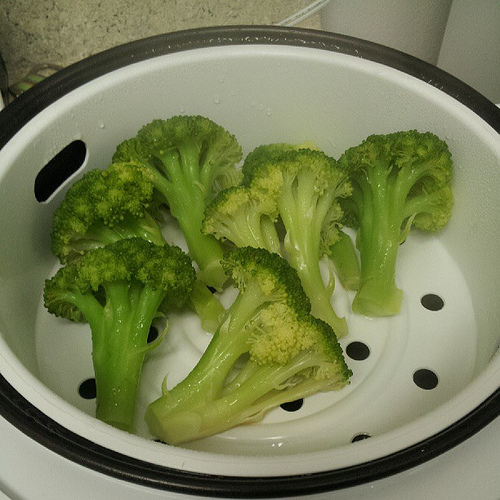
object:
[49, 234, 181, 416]
broccoli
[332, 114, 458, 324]
broccoli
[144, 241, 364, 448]
broccoli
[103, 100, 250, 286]
broccoli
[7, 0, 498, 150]
reflection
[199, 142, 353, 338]
broccoli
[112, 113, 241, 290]
broccoli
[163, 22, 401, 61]
rim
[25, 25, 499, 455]
steamer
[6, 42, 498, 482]
bowl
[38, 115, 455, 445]
broccoli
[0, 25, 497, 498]
steamer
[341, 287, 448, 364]
steam holes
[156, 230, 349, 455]
green broccoli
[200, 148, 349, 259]
broccoli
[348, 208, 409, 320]
stem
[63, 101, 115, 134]
water drops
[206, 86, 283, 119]
water drops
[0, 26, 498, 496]
steam bowl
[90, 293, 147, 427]
stem piece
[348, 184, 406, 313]
stem piece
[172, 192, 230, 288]
stem piece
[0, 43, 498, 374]
coating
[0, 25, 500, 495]
vegetable steamer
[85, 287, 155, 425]
stem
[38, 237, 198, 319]
head piece